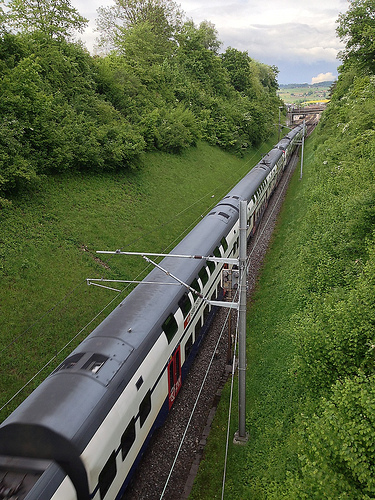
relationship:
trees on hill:
[0, 2, 285, 203] [0, 123, 270, 391]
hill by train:
[0, 101, 286, 430] [2, 118, 307, 496]